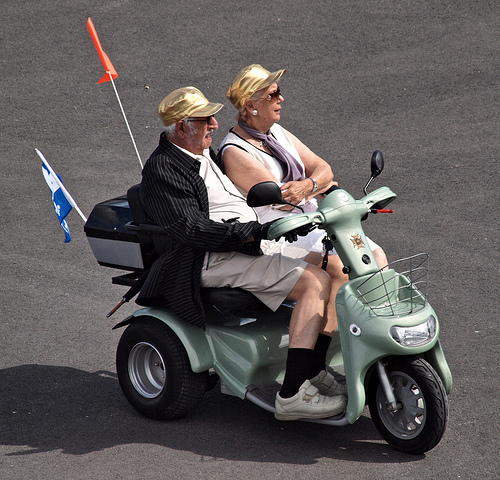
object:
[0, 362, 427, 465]
shadow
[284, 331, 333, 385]
sock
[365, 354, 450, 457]
wheel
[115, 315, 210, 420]
wheel